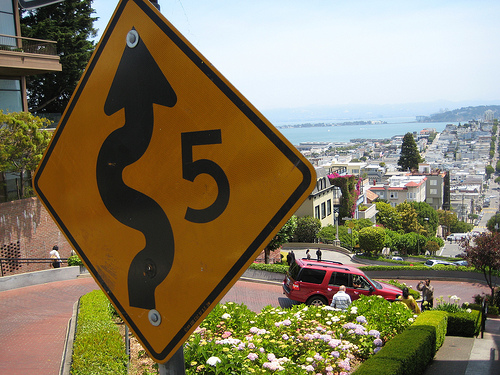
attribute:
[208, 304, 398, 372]
flowers — pink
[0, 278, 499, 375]
road — pink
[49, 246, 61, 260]
shirt — white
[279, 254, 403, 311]
suv — red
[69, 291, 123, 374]
grass — green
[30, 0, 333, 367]
sign — yellow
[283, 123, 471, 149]
ocean — blue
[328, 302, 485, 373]
hedges — green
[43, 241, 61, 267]
woman — walking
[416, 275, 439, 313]
person — standing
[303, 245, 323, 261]
people — looking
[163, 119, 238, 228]
number — black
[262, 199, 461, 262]
trees — green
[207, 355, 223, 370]
flower — white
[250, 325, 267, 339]
flower — white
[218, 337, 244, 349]
flower — white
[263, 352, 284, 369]
flower — white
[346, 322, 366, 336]
flower — white